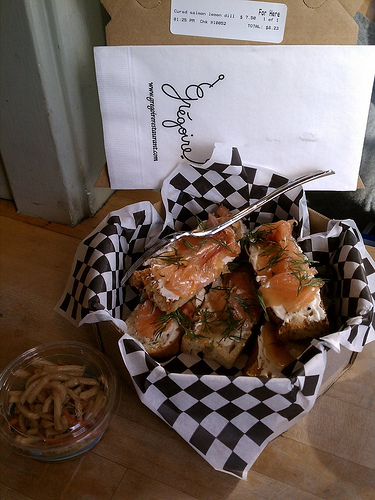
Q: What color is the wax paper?
A: Black and white.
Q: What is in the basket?
A: Food.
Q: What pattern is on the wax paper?
A: Checkered.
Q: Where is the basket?
A: On the table.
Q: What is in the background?
A: A white bag.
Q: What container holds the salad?
A: A plastic container.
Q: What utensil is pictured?
A: A fork.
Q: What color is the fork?
A: Silver.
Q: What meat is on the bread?
A: Salmon.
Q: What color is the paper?
A: Black and white.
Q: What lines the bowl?
A: Paper.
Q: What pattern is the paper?
A: Checked.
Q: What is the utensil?
A: Fork.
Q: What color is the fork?
A: Silver.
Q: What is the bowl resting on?
A: Table.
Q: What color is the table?
A: Brown.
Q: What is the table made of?
A: Wood.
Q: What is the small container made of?
A: Plastic.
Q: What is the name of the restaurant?
A: Gregoire's.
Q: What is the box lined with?
A: Paper.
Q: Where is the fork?
A: In box.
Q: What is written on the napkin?
A: Gregoire.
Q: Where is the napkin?
A: Behind the food box.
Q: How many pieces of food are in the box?
A: 5.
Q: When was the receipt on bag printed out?
A: 1:25 pm.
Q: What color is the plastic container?
A: Clear.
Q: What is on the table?
A: A basket.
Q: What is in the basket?
A: Food.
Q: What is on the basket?
A: Sandwiches.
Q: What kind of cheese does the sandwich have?
A: Cream cheese.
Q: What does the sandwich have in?
A: Slices of meat.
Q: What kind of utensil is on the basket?
A: Spoon.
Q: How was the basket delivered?
A: By mail.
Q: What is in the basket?
A: Ham.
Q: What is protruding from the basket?
A: A fork.